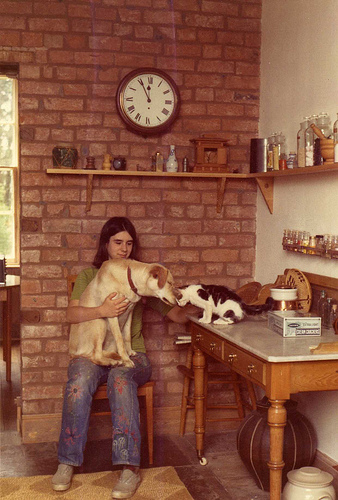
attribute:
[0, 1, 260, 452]
wall — brick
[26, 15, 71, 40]
brick — red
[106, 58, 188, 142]
clock — round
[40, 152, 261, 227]
shelf — wood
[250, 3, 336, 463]
wall — white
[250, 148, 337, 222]
shelf — wood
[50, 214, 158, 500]
girl — sitting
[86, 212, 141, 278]
hair — short, dark, combed, parted, neat, brown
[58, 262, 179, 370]
shirt — green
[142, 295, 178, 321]
sleeve — short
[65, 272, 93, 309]
sleeve — short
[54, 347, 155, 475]
jeans — blue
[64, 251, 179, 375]
dog — sitting, brown